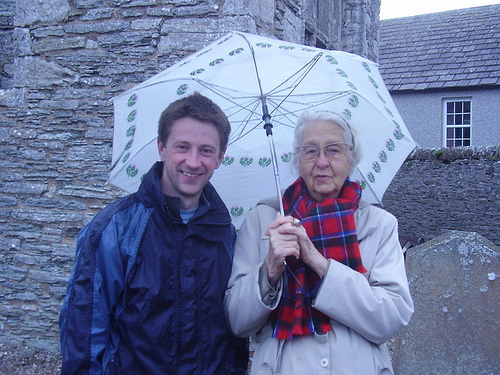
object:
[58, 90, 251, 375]
man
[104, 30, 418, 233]
umbrella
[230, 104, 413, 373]
woman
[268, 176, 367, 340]
scarf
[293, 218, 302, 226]
ring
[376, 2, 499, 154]
house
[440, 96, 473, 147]
window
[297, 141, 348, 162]
glasses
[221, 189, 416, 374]
jacket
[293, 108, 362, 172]
hair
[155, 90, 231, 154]
hair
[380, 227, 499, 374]
wall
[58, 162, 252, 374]
coat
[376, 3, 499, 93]
roof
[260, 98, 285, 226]
pole